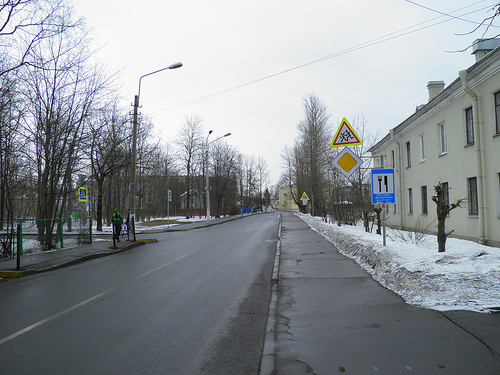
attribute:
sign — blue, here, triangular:
[371, 169, 396, 206]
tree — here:
[433, 184, 466, 252]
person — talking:
[111, 208, 123, 248]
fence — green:
[1, 216, 92, 257]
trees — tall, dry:
[0, 3, 385, 261]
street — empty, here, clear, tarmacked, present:
[4, 209, 500, 375]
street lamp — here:
[129, 61, 184, 241]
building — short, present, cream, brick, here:
[369, 36, 499, 247]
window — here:
[465, 105, 476, 148]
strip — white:
[0, 213, 275, 348]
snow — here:
[294, 209, 500, 313]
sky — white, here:
[0, 1, 499, 199]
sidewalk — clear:
[1, 236, 157, 278]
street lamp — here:
[205, 129, 232, 220]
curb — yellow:
[135, 238, 159, 245]